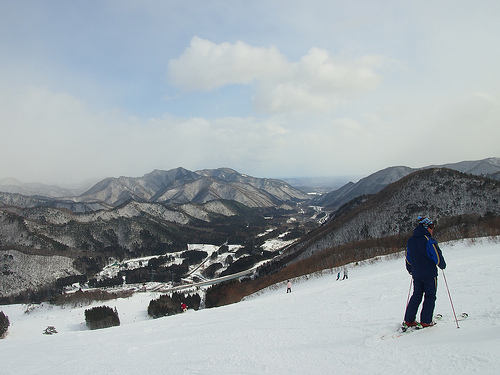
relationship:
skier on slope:
[393, 213, 448, 335] [1, 231, 498, 373]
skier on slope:
[338, 263, 353, 283] [1, 231, 498, 373]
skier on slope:
[333, 263, 343, 281] [1, 231, 498, 373]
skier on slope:
[281, 274, 295, 296] [1, 231, 498, 373]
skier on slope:
[176, 300, 191, 319] [1, 231, 498, 373]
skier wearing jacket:
[176, 300, 191, 319] [178, 302, 188, 307]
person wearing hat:
[402, 212, 447, 338] [416, 214, 440, 227]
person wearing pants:
[402, 212, 447, 338] [407, 280, 437, 326]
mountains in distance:
[2, 157, 497, 297] [3, 58, 498, 262]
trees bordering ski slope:
[346, 246, 368, 260] [264, 242, 384, 305]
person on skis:
[402, 212, 447, 338] [399, 311, 468, 333]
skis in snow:
[371, 312, 444, 341] [16, 269, 498, 374]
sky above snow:
[1, 1, 499, 188] [3, 190, 498, 373]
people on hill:
[281, 262, 355, 297] [102, 245, 495, 375]